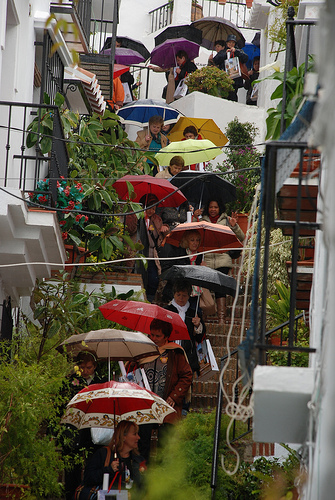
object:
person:
[242, 55, 260, 107]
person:
[191, 192, 246, 325]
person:
[116, 317, 193, 465]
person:
[45, 348, 108, 499]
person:
[156, 202, 188, 230]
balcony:
[31, 0, 120, 102]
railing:
[148, 0, 175, 15]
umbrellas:
[189, 15, 247, 55]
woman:
[172, 53, 196, 89]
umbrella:
[149, 36, 201, 70]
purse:
[74, 444, 111, 499]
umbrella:
[110, 174, 188, 212]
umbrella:
[166, 115, 230, 160]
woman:
[135, 114, 171, 175]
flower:
[273, 232, 285, 253]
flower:
[68, 199, 75, 208]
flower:
[84, 254, 107, 271]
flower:
[56, 172, 66, 190]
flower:
[277, 245, 284, 257]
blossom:
[75, 214, 89, 221]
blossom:
[75, 180, 85, 193]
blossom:
[37, 193, 47, 205]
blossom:
[27, 190, 35, 199]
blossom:
[58, 217, 65, 226]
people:
[138, 192, 166, 303]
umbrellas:
[154, 263, 245, 318]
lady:
[160, 229, 204, 274]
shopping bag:
[194, 336, 220, 380]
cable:
[0, 164, 261, 217]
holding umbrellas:
[189, 16, 246, 71]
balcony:
[0, 99, 71, 211]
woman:
[125, 316, 188, 462]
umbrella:
[97, 297, 191, 341]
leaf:
[50, 451, 58, 458]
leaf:
[36, 379, 48, 386]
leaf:
[97, 237, 114, 259]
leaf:
[48, 306, 61, 315]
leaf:
[26, 339, 35, 346]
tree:
[0, 306, 94, 498]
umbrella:
[153, 138, 223, 166]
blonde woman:
[133, 115, 168, 179]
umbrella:
[116, 97, 181, 135]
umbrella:
[165, 170, 238, 208]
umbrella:
[100, 46, 146, 64]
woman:
[128, 316, 193, 464]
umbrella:
[59, 379, 178, 461]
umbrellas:
[55, 327, 163, 381]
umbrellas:
[66, 380, 167, 423]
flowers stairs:
[25, 174, 88, 242]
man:
[174, 49, 198, 90]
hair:
[107, 418, 140, 455]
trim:
[112, 104, 180, 125]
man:
[112, 58, 125, 110]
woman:
[161, 278, 206, 413]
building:
[208, 0, 334, 498]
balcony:
[252, 139, 334, 443]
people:
[83, 418, 140, 498]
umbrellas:
[239, 42, 261, 70]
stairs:
[192, 254, 262, 409]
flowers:
[115, 216, 125, 233]